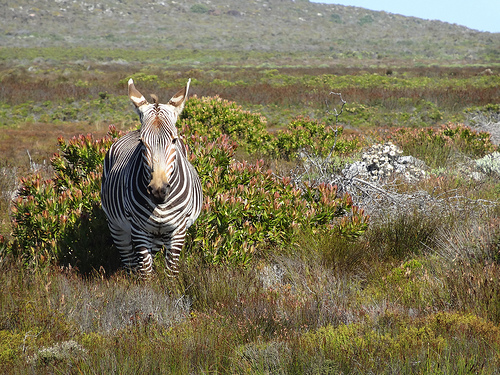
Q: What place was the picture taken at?
A: It was taken at the field.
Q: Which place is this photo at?
A: It is at the field.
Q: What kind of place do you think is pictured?
A: It is a field.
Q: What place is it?
A: It is a field.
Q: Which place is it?
A: It is a field.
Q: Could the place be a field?
A: Yes, it is a field.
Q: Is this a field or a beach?
A: It is a field.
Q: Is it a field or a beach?
A: It is a field.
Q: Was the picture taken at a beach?
A: No, the picture was taken in a field.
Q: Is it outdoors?
A: Yes, it is outdoors.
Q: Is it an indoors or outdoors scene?
A: It is outdoors.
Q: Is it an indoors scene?
A: No, it is outdoors.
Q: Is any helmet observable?
A: No, there are no helmets.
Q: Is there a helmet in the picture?
A: No, there are no helmets.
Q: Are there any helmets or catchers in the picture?
A: No, there are no helmets or catchers.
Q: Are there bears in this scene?
A: No, there are no bears.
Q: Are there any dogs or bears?
A: No, there are no bears or dogs.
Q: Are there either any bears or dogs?
A: No, there are no bears or dogs.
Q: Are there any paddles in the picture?
A: No, there are no paddles.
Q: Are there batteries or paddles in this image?
A: No, there are no paddles or batteries.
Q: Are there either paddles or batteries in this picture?
A: No, there are no paddles or batteries.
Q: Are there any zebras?
A: Yes, there is a zebra.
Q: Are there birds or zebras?
A: Yes, there is a zebra.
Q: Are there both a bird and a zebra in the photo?
A: No, there is a zebra but no birds.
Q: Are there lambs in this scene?
A: No, there are no lambs.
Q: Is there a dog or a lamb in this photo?
A: No, there are no lambs or dogs.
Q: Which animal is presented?
A: The animal is a zebra.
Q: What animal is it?
A: The animal is a zebra.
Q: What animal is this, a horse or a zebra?
A: This is a zebra.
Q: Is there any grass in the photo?
A: Yes, there is grass.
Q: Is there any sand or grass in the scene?
A: Yes, there is grass.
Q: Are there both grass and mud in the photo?
A: No, there is grass but no mud.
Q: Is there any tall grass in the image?
A: Yes, there is tall grass.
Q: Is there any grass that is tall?
A: Yes, there is grass that is tall.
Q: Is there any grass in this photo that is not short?
A: Yes, there is tall grass.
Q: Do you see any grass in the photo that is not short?
A: Yes, there is tall grass.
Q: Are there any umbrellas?
A: No, there are no umbrellas.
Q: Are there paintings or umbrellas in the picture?
A: No, there are no umbrellas or paintings.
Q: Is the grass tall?
A: Yes, the grass is tall.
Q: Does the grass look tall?
A: Yes, the grass is tall.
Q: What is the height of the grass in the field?
A: The grass is tall.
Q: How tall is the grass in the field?
A: The grass is tall.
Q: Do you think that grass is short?
A: No, the grass is tall.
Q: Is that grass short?
A: No, the grass is tall.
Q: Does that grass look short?
A: No, the grass is tall.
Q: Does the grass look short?
A: No, the grass is tall.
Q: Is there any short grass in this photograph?
A: No, there is grass but it is tall.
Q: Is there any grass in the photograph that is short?
A: No, there is grass but it is tall.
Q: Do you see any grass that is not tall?
A: No, there is grass but it is tall.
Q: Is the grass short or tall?
A: The grass is tall.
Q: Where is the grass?
A: The grass is in the field.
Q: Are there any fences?
A: No, there are no fences.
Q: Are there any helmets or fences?
A: No, there are no fences or helmets.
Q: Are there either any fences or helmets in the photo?
A: No, there are no fences or helmets.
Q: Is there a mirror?
A: No, there are no mirrors.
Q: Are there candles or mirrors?
A: No, there are no mirrors or candles.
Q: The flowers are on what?
A: The flowers are on the bush.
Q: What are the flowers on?
A: The flowers are on the bush.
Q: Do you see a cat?
A: No, there are no cats.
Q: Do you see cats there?
A: No, there are no cats.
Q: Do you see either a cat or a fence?
A: No, there are no cats or fences.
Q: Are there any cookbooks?
A: No, there are no cookbooks.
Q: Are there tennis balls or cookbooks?
A: No, there are no cookbooks or tennis balls.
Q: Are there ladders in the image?
A: No, there are no ladders.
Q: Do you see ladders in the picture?
A: No, there are no ladders.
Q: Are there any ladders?
A: No, there are no ladders.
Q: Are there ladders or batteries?
A: No, there are no ladders or batteries.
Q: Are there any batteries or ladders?
A: No, there are no ladders or batteries.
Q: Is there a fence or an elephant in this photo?
A: No, there are no fences or elephants.